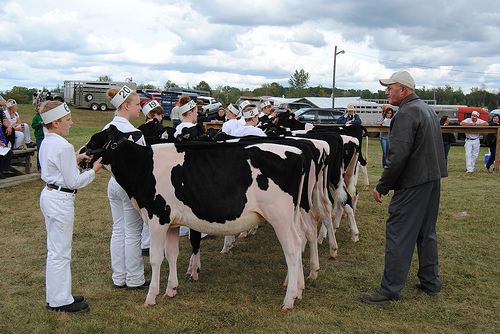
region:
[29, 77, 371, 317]
kids with numbers on their head lined up with cows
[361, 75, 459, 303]
a man in gray wearing a baseball cap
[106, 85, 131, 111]
a number 20 on headband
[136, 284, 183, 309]
a cow's front hoofs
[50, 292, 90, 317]
a boy's shoes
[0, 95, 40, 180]
people sitting in bleachers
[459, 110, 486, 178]
a man standing behind a long wooden table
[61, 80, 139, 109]
an animal transporting vehicle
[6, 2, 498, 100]
a cloud covered sky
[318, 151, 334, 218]
the tail of a cow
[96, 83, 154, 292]
Girl wearing number 20 head band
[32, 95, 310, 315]
Boy in white holding on to cow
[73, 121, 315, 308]
Black and white cow standing on grass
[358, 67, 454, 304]
Man in gray baseball hat, black jacket and black pants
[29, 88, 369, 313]
Line of kids holding on to cows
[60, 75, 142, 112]
Silver trailer with 3 visible wheels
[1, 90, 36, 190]
Two people sitting on stand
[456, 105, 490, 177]
Man in white leaning on fence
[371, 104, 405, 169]
Woman in blue jeans and sunglasses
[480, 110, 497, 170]
Woman standing in front of blue cooler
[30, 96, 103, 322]
The boy on the left.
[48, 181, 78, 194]
The black belt the boy is wearing.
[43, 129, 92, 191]
The shirt the boy is wearing.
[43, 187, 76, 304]
The pants the boy is wearing.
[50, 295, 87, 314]
The black boots the boy is wearing.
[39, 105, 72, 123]
The headband the boy is wearing.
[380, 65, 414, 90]
The hat the man is wearing.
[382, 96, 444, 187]
The leather jacket the man is wearing.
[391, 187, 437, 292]
The gray pants the man is wearing.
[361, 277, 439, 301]
The boots the man is wearing.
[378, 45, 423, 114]
the head of a man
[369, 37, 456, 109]
a man wearing a hat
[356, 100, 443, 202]
the arm of a man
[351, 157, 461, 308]
the legs of a man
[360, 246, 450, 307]
the feet of a man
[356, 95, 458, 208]
a man wearing a jacket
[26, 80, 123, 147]
the head of a boy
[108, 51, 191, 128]
the head of a girl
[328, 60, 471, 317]
a man standing on grass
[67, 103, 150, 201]
the head of a cow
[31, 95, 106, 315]
the boy is standing next to a cow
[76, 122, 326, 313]
the black and white cow is standing next to boy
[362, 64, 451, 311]
the man with the grey hat is standing behind cows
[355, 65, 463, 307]
the man is wearing a black jacket and grey pants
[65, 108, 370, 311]
the row of black and white cows are in the center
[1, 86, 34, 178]
spectators are sitting in the stands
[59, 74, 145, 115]
the truck in the background transports the cows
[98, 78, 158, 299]
the red head girl has a 20 on her headband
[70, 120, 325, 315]
the cow is cooperative around the boy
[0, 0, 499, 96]
the clouds in the sky are light and dark